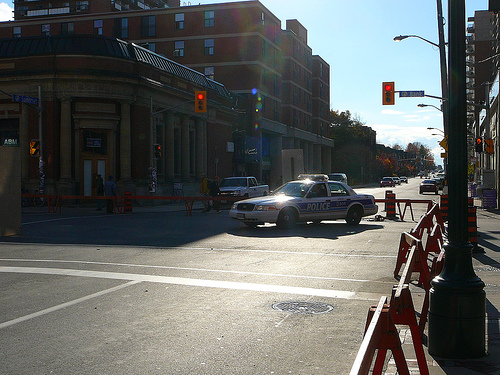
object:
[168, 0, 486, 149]
sky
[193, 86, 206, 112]
light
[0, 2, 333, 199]
building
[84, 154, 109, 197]
doors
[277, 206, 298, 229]
tire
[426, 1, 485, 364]
pole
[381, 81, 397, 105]
light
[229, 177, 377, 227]
car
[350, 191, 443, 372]
barricade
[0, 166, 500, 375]
road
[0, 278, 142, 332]
lines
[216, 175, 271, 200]
truck